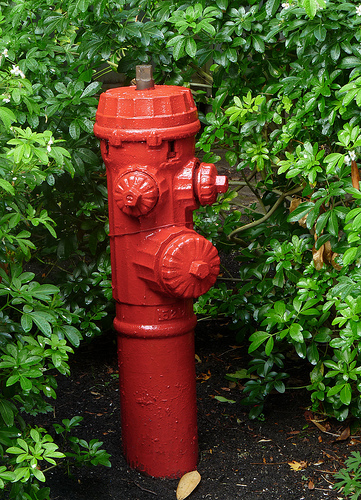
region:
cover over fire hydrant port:
[156, 227, 223, 301]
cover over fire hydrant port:
[112, 167, 158, 213]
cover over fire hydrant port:
[191, 153, 233, 205]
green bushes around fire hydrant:
[1, 1, 359, 491]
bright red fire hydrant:
[96, 83, 221, 479]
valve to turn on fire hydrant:
[133, 63, 158, 91]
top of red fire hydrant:
[96, 85, 204, 141]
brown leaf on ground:
[173, 468, 204, 498]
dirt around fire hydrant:
[66, 338, 307, 498]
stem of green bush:
[225, 175, 301, 247]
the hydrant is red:
[64, 65, 193, 448]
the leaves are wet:
[216, 180, 314, 392]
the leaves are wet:
[4, 225, 94, 403]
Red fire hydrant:
[90, 60, 234, 483]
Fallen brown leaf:
[169, 467, 212, 498]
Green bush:
[230, 66, 360, 366]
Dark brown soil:
[203, 418, 287, 498]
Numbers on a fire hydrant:
[153, 302, 189, 322]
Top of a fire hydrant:
[91, 59, 204, 149]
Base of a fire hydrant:
[104, 319, 218, 483]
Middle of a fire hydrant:
[94, 146, 236, 305]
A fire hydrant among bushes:
[78, 57, 238, 487]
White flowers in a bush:
[0, 48, 27, 105]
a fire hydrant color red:
[84, 45, 238, 479]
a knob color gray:
[127, 59, 156, 93]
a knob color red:
[210, 170, 229, 191]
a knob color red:
[185, 255, 214, 282]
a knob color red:
[118, 183, 143, 208]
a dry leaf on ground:
[168, 465, 209, 498]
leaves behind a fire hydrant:
[0, 0, 357, 494]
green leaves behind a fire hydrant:
[2, 2, 350, 494]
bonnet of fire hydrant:
[85, 84, 203, 144]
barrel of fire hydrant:
[103, 146, 202, 478]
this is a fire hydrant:
[82, 63, 243, 486]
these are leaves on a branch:
[264, 300, 331, 356]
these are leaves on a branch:
[314, 360, 359, 416]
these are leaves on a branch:
[323, 276, 359, 338]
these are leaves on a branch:
[13, 268, 65, 329]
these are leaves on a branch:
[4, 207, 39, 271]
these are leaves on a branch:
[9, 130, 66, 201]